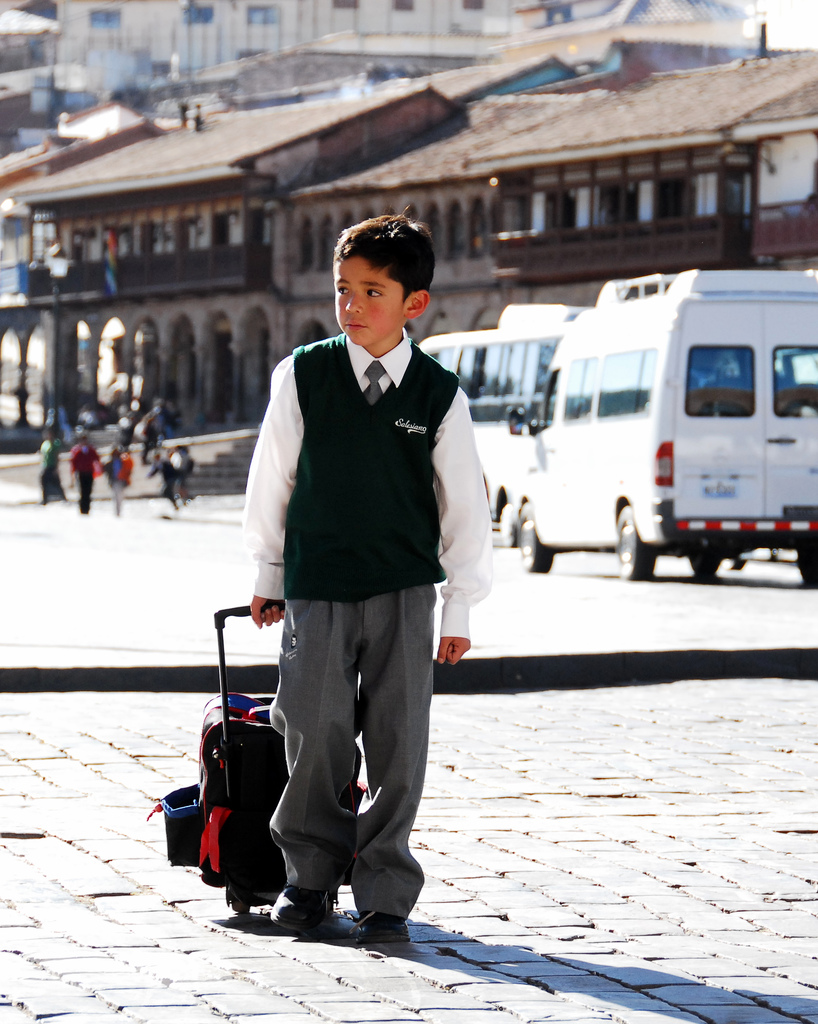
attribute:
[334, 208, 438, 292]
hair — brown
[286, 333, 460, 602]
vest — green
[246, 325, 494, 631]
shirt — white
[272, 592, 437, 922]
slacks — grey